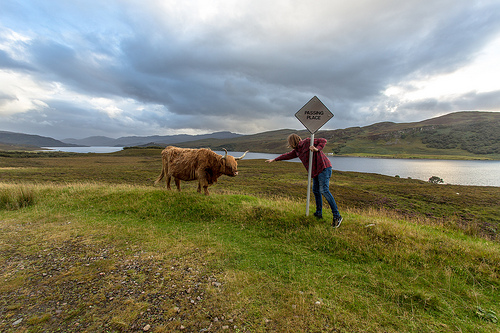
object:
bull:
[153, 144, 250, 197]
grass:
[0, 149, 495, 333]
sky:
[0, 0, 500, 135]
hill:
[76, 132, 115, 140]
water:
[35, 138, 128, 155]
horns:
[219, 145, 231, 156]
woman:
[264, 131, 344, 228]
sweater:
[278, 138, 338, 176]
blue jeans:
[312, 167, 342, 219]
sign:
[294, 93, 334, 134]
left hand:
[304, 143, 320, 154]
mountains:
[336, 110, 499, 153]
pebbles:
[140, 322, 152, 332]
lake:
[192, 148, 500, 190]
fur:
[165, 145, 214, 179]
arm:
[272, 150, 296, 162]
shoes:
[328, 215, 345, 230]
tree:
[427, 174, 445, 187]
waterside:
[251, 157, 500, 189]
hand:
[263, 158, 277, 165]